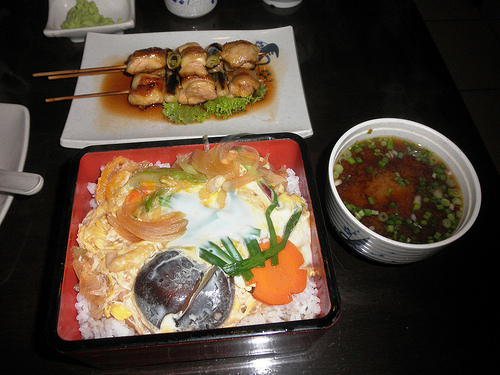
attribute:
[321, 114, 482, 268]
bowl — white, small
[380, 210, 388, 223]
onion — green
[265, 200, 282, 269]
bean — green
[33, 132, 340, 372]
dish — square, black, orange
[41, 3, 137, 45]
dish — white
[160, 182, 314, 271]
liquid — cream, milky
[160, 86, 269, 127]
garnish — green, lettuce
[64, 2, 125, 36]
wasabi — green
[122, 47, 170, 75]
meat — fried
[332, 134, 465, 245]
miso soup — brown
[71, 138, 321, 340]
food — japanese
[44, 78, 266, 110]
skewer — wooden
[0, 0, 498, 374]
table — brown, wooden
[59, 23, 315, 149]
plate — flat, white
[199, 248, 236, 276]
bean — green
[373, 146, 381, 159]
onion — green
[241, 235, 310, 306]
circle — orange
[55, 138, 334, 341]
lining — red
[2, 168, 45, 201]
utensil — white